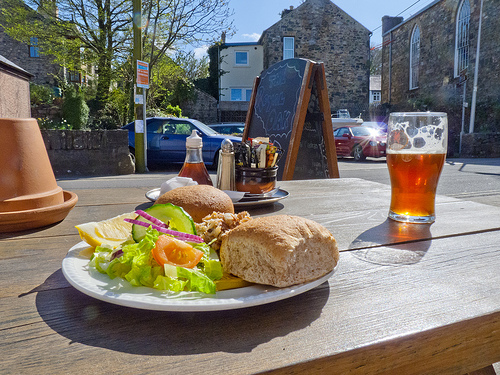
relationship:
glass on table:
[363, 87, 454, 238] [254, 107, 466, 372]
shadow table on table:
[338, 220, 440, 270] [54, 145, 484, 354]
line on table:
[354, 234, 391, 268] [0, 177, 498, 371]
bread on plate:
[227, 224, 374, 269] [118, 300, 267, 324]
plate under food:
[66, 208, 337, 314] [109, 209, 296, 276]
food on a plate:
[74, 184, 341, 296] [63, 236, 335, 313]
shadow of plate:
[37, 282, 333, 358] [52, 203, 343, 318]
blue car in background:
[119, 116, 243, 170] [158, 85, 467, 206]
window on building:
[233, 51, 249, 65] [188, 40, 268, 117]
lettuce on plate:
[81, 220, 221, 298] [63, 236, 335, 313]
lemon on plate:
[71, 207, 143, 247] [63, 236, 335, 313]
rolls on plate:
[153, 182, 343, 277] [53, 197, 365, 312]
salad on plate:
[113, 191, 237, 315] [50, 222, 340, 316]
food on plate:
[66, 181, 336, 290] [60, 228, 333, 321]